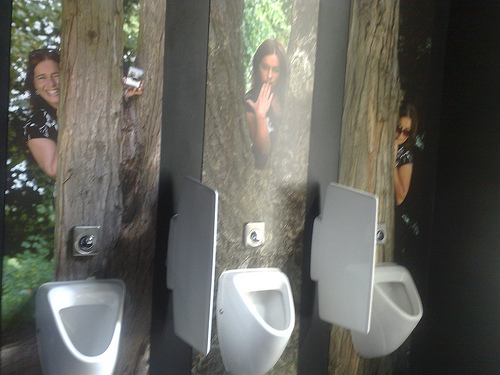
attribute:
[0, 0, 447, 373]
wall — dark